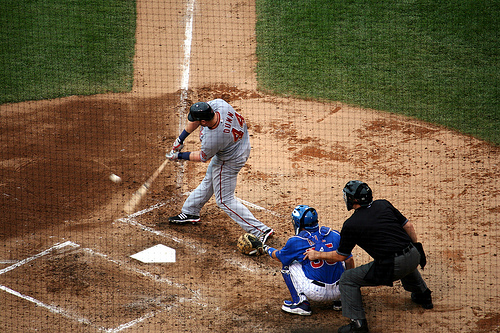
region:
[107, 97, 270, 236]
man is playing baseball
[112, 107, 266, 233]
man is holding a bat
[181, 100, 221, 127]
man is wearing a black baseball helmet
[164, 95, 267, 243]
man is wearing a gray uniform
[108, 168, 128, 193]
ball i sin the air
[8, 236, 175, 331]
rectangle box painted in dirt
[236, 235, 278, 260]
man is holding baseball glove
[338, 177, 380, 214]
person is wearing a face mask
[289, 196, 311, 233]
person is wearing a face mask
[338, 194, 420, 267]
person is wearing a black shirt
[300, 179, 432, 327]
an umpire on a baseball field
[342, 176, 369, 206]
the black helmet of an ump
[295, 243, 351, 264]
the arm of an umpire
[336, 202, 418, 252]
the black shirt of the ump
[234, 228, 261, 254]
the glove of the catcher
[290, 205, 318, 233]
the blue helmet of the catcher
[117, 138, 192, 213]
the wooden bat in motion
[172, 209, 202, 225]
the black and white shoe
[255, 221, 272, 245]
the black and white shoe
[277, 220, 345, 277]
the red and blue shirt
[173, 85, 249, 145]
the head of of a man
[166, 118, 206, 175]
the hands of a man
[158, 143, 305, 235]
the legs of a man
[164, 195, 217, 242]
the foot of a man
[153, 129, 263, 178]
the arm of a man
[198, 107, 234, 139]
the neck of a man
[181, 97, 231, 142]
a man wearing a hat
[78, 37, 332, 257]
a man swinging a bat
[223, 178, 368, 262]
a man wearing a glove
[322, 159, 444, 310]
a man wearing a face gaurd